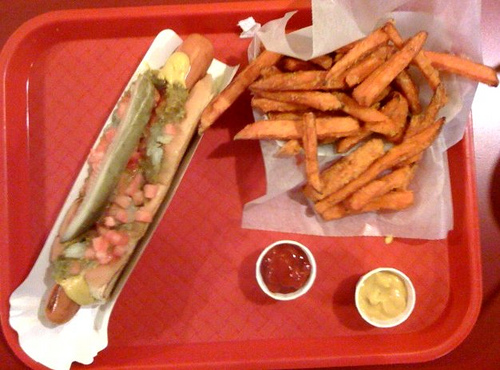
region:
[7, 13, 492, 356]
food on red tray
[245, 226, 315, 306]
small white cup with ketchup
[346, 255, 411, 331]
small white cup with mustard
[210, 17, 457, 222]
order of sweet potato fries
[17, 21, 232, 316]
foot long hot dog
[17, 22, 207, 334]
hot dog with tomatoes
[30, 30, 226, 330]
hot dog with mustard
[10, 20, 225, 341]
hot dog in paper tray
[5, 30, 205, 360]
hot dog with relish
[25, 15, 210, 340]
hot dog with pickle spear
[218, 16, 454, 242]
french fries on a tray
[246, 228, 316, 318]
ketchup in a cup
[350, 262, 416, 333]
mustard in a cup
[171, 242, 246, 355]
red tray of food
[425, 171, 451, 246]
white paper under fries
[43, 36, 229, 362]
hotdog on a paper tray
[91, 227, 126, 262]
tomatoes on a hotdog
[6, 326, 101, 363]
white tray under hotdog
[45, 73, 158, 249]
pickle on a hotdog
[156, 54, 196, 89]
mustard on a hotdog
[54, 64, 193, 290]
long hot dog in bun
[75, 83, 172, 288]
red chopped tomatoes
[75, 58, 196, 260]
green relish on hot dog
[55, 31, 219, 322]
yellow mustard on hot dog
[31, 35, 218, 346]
hot dog in white paper plate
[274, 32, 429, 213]
orange sweet potato fries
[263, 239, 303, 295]
souffle cup with ketchup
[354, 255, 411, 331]
souffle cup with mustard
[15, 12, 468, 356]
food in red tray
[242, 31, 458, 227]
sweet potato fries in parchment paper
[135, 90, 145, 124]
the pickle is green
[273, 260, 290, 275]
the ketchup is red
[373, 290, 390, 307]
the mustard is yellow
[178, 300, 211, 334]
the tray is red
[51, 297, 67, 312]
the hotdog is brown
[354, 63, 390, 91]
the ffries are brown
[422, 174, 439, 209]
the paper is white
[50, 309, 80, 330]
the hotdog is in the holder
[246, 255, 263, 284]
the container is on the tray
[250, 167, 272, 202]
the paper is on the tray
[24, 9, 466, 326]
this is a lunch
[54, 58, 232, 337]
this is a hot dog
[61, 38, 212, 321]
the hot dog has lots of toppings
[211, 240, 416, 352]
these are condiments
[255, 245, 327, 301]
this is tomato ketchup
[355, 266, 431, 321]
this mustard is light yellow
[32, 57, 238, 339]
the hot dog is very long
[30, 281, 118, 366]
the hot dog is pink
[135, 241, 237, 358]
this is a lunch tray